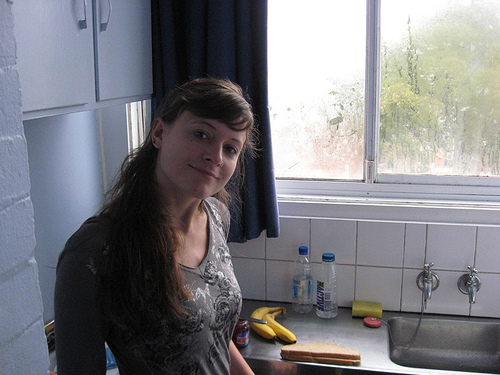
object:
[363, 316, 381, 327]
red stopper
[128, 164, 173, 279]
hair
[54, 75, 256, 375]
woman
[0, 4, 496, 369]
kitchen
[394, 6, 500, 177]
streaks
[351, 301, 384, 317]
sponge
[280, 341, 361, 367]
sandwich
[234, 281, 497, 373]
counter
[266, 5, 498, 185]
window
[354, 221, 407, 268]
tile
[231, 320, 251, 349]
container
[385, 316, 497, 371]
sink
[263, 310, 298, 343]
banana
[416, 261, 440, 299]
faucet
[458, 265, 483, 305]
faucet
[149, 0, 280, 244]
curtain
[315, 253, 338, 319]
bottle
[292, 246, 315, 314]
bottle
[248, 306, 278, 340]
banana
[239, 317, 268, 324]
knife